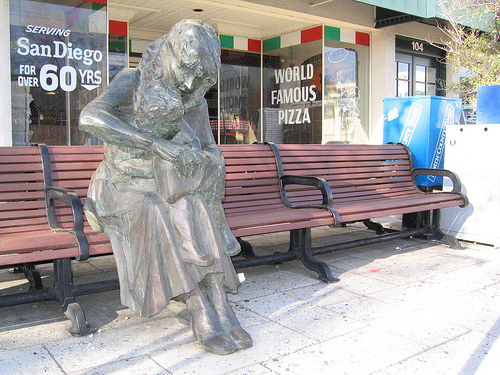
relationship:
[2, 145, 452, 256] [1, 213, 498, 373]
benches on sidewalk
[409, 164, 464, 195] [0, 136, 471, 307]
armrests on bench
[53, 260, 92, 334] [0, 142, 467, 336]
leg on bench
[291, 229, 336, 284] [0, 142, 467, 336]
leg on bench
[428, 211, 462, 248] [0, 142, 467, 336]
leg on bench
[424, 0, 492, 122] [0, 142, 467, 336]
tree behind bench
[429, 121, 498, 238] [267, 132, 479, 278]
box near bench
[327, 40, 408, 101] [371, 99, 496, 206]
door behind dispenser